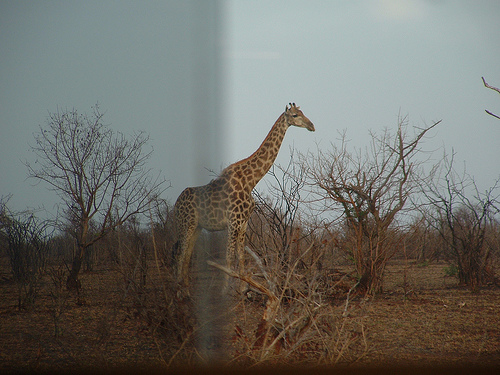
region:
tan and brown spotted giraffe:
[150, 85, 314, 292]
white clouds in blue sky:
[16, 9, 93, 57]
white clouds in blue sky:
[110, 21, 191, 88]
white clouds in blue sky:
[173, 91, 210, 126]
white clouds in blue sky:
[159, 75, 200, 129]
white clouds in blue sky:
[182, 16, 247, 67]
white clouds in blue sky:
[266, 29, 320, 76]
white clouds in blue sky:
[355, 23, 417, 87]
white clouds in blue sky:
[386, 22, 447, 90]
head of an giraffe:
[261, 99, 321, 143]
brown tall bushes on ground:
[187, 266, 323, 341]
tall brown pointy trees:
[308, 118, 466, 290]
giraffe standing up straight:
[150, 98, 317, 305]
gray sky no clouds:
[53, 49, 448, 131]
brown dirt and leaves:
[35, 253, 153, 350]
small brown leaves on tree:
[36, 103, 107, 168]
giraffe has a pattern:
[224, 175, 275, 229]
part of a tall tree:
[456, 56, 498, 116]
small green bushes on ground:
[421, 245, 463, 283]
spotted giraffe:
[138, 88, 321, 309]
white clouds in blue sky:
[76, 45, 144, 85]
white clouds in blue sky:
[159, 25, 204, 90]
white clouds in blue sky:
[158, 123, 218, 165]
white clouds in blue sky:
[3, 124, 30, 167]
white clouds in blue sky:
[316, 21, 367, 89]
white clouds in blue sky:
[373, 0, 437, 59]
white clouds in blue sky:
[410, 48, 455, 103]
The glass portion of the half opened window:
[0, 1, 236, 370]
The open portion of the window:
[218, 1, 499, 373]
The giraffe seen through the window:
[157, 98, 319, 309]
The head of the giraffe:
[279, 96, 324, 136]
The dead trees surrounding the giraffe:
[2, 75, 497, 373]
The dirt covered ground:
[2, 256, 499, 373]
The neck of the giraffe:
[234, 115, 289, 192]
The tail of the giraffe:
[165, 202, 183, 265]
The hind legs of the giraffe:
[177, 203, 200, 293]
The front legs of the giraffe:
[218, 214, 254, 294]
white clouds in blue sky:
[17, 65, 92, 108]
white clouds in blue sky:
[1, 140, 41, 185]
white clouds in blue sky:
[81, 17, 151, 68]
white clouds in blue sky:
[302, 68, 364, 111]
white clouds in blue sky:
[351, 23, 391, 80]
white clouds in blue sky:
[397, 13, 471, 79]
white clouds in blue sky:
[393, 58, 435, 100]